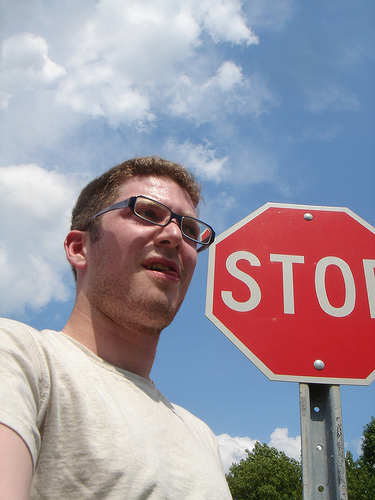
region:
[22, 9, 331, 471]
a scene during the day time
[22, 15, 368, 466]
a scene outside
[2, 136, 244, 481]
a person standing with glasses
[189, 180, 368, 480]
a stop sign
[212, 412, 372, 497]
green trees in the background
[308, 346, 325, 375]
a silver bolt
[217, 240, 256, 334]
White letter on a red sign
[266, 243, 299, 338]
White letter on a red sign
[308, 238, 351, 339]
White letter on a red sign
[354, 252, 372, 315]
White letter on a red sign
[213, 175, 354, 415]
Red and white sign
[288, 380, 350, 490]
Large metal post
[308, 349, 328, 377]
Metal screw on a pole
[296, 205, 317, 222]
Metal screw on a pole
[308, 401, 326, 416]
Small hole in a metal pole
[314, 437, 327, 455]
Small hole in a metal pole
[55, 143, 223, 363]
man is wearing eyeglasses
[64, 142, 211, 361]
man is wearing eyeglasses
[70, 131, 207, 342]
man is wearing eyeglasses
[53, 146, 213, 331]
man is wearing eyeglasses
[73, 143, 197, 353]
man is wearing eyeglasses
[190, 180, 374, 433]
a red STOP sign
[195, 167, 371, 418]
a red STOP sign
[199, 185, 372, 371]
a red STOP sign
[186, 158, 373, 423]
a red STOP sign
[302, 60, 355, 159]
Small white cloud in the blue sky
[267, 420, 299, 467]
Small white cloud in the blue sky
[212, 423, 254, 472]
Small white cloud in the blue sky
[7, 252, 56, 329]
Small white cloud in the blue sky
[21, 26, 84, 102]
Small white cloud in the blue sky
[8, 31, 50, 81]
Small white cloud in the blue sky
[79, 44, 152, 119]
Small white cloud in the blue sky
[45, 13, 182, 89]
Small white cloud in the blue sky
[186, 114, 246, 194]
Small white cloud in the blue sky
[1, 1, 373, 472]
white clouds in blue sky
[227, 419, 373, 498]
green leaves on trees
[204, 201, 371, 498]
stop sign on pole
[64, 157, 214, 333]
glasses on man's face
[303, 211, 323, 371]
two bolts on stop sign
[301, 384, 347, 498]
metal pole with holes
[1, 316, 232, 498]
white tee shirt on man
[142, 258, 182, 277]
tongue sticking out of mouth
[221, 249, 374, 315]
white letters on red sign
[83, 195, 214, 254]
black frame on glasses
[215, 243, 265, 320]
This is a letter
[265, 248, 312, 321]
This is a letter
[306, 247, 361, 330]
This is a letter